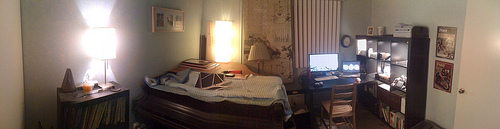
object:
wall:
[291, 0, 340, 71]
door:
[451, 0, 498, 128]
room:
[0, 1, 498, 127]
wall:
[20, 17, 70, 79]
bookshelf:
[354, 34, 428, 129]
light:
[357, 39, 367, 55]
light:
[378, 66, 390, 79]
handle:
[457, 88, 467, 93]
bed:
[132, 74, 281, 129]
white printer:
[393, 23, 428, 38]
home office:
[160, 21, 449, 95]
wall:
[406, 15, 490, 126]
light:
[81, 27, 119, 59]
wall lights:
[215, 20, 232, 61]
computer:
[307, 53, 339, 72]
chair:
[317, 83, 357, 128]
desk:
[306, 74, 378, 112]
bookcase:
[55, 88, 131, 127]